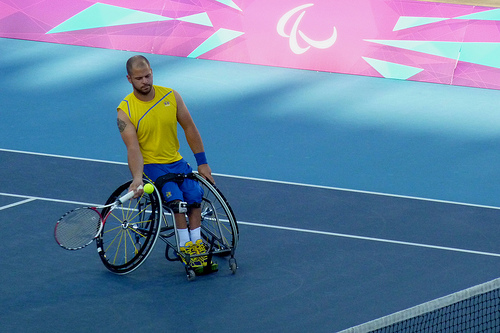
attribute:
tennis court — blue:
[6, 39, 496, 322]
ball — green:
[134, 174, 165, 211]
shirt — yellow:
[113, 88, 188, 161]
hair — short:
[127, 54, 151, 74]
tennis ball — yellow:
[133, 175, 160, 203]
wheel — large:
[67, 190, 180, 273]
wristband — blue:
[191, 149, 208, 167]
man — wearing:
[116, 55, 216, 268]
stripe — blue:
[134, 88, 173, 137]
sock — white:
[190, 224, 203, 246]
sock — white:
[172, 227, 193, 251]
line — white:
[3, 146, 499, 214]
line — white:
[0, 187, 497, 259]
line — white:
[0, 194, 35, 214]